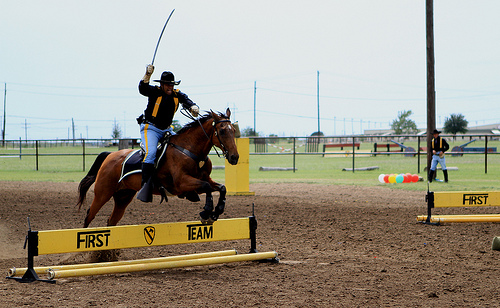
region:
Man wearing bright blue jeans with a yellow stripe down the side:
[130, 56, 189, 172]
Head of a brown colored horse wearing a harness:
[207, 111, 238, 163]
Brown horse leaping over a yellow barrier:
[76, 105, 240, 231]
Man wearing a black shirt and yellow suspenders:
[419, 123, 460, 183]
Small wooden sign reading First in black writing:
[421, 190, 498, 208]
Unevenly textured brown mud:
[313, 221, 488, 298]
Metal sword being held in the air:
[137, 2, 176, 79]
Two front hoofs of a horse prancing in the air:
[186, 185, 233, 225]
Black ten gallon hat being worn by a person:
[152, 68, 189, 89]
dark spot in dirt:
[321, 202, 342, 223]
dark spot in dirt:
[356, 254, 398, 279]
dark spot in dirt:
[401, 280, 450, 302]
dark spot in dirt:
[259, 259, 309, 278]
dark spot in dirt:
[239, 279, 264, 304]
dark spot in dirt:
[285, 180, 322, 208]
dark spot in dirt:
[263, 204, 291, 224]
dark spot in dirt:
[269, 219, 297, 240]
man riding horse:
[35, 4, 282, 283]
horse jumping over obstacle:
[26, 162, 273, 304]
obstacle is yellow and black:
[9, 202, 291, 297]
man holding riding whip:
[62, 12, 244, 229]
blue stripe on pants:
[134, 118, 167, 165]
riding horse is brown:
[67, 90, 248, 264]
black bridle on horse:
[149, 84, 224, 189]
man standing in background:
[378, 105, 463, 215]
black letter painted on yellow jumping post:
[100, 230, 110, 248]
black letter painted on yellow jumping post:
[86, 233, 97, 253]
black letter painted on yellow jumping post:
[82, 233, 89, 252]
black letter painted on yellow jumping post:
[188, 224, 199, 244]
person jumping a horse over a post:
[65, 14, 285, 238]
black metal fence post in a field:
[345, 134, 360, 176]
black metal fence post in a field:
[288, 138, 300, 174]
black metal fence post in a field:
[480, 135, 490, 176]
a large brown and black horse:
[72, 105, 248, 232]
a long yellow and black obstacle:
[14, 213, 263, 290]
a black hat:
[151, 66, 185, 86]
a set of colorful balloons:
[375, 172, 425, 184]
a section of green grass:
[295, 153, 498, 192]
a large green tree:
[443, 115, 466, 137]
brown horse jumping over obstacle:
[71, 108, 256, 220]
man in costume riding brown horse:
[131, 60, 193, 170]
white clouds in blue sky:
[80, 20, 111, 45]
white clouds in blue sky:
[25, 68, 51, 90]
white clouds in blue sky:
[67, 57, 109, 99]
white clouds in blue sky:
[198, 23, 206, 33]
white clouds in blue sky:
[210, 57, 235, 79]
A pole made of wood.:
[423, 6, 438, 171]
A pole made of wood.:
[315, 65, 323, 141]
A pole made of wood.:
[78, 135, 89, 167]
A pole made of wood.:
[27, 138, 47, 173]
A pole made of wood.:
[36, 147, 88, 159]